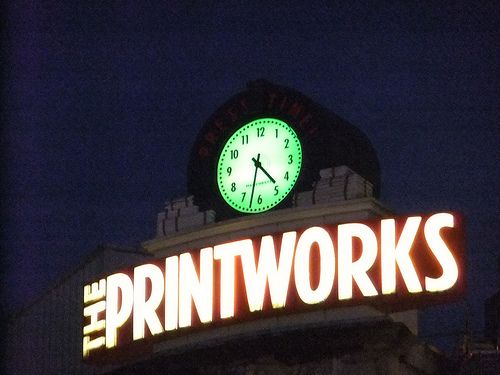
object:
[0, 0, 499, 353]
sky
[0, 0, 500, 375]
photo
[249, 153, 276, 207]
hand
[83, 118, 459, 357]
light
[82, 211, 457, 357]
sign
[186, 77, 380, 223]
edge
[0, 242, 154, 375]
cables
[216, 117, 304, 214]
clock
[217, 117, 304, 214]
clockface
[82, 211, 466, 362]
text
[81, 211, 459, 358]
glow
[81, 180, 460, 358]
letters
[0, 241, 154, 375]
side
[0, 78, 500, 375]
building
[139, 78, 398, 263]
top